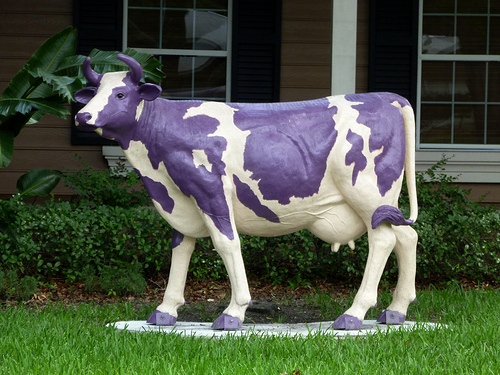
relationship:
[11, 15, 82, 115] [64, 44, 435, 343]
bushes behind cow statue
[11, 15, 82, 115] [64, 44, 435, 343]
leaves behind cow statue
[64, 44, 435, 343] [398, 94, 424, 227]
cow statue has tail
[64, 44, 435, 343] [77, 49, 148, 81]
cow statue has horns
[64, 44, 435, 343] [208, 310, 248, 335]
cow statue has hoof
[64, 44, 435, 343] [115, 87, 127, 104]
cow statue has eye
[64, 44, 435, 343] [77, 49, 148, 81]
"cow has black horns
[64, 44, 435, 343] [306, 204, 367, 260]
cow has white udders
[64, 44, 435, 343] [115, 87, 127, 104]
cow has black eyes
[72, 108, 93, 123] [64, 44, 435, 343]
nose of cow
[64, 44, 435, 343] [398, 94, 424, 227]
cow has white tail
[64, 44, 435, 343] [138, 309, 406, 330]
cow has four hooves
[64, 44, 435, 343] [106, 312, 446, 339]
cow stands on platform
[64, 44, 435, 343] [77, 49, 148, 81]
cow has horns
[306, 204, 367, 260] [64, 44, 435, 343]
udder under cow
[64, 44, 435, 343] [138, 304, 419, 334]
cow has four hooves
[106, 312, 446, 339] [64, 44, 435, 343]
platform under cow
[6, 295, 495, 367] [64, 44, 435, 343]
grass under cow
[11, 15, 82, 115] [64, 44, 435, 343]
bushes behind a cow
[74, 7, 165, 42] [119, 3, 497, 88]
shutters on window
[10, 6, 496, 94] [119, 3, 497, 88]
house has a window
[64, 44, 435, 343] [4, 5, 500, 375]
statue in garden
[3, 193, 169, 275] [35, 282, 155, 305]
hedge on top wood chips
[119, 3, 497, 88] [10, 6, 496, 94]
window has shutter sets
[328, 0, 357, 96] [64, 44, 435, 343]
pole behind cow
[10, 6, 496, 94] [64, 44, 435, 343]
building behind cow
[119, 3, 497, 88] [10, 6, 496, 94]
windows are in building